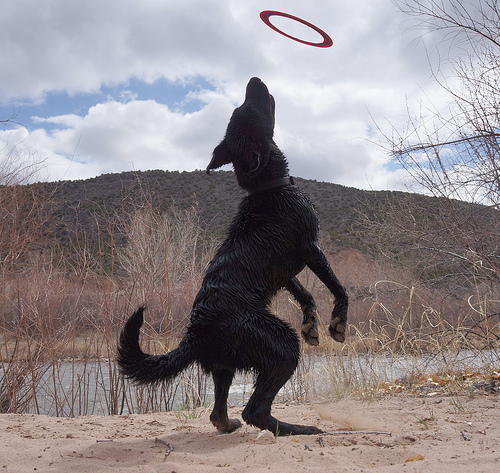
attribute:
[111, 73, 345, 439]
black dog — medium-sized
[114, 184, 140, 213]
branch — leafless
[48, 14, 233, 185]
sky — blue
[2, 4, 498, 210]
sky — blue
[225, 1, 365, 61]
disc — red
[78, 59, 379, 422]
dog — black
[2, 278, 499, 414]
stalks — tall, dried-out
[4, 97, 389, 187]
puffy clouds — white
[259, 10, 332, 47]
frisbee — red, black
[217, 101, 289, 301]
black dog — wet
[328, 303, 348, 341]
paw — sandy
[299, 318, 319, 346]
paw — sandy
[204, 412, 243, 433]
paw — sandy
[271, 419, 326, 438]
paw — sandy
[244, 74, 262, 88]
nose — black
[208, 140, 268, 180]
ears — black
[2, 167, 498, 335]
hills — gray, green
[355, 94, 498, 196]
branch — bare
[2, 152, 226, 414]
trees — leafless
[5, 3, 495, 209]
clouds — dense, gray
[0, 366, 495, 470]
soil — sandy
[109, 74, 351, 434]
dog — black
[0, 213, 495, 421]
grass — brown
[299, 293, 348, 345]
paws — black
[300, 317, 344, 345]
pads — brown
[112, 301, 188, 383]
tail — black